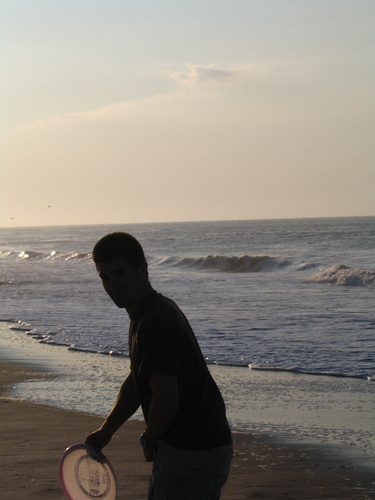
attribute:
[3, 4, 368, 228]
sky — blue, white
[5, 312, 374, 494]
shore — sandy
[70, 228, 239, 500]
man — playing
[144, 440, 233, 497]
shorts — grey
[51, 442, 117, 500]
frisbee — clear, transparent, pink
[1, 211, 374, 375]
ocean — blue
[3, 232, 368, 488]
beach — sandy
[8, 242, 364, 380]
waves — white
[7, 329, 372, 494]
sand — brown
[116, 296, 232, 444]
shirt — brown